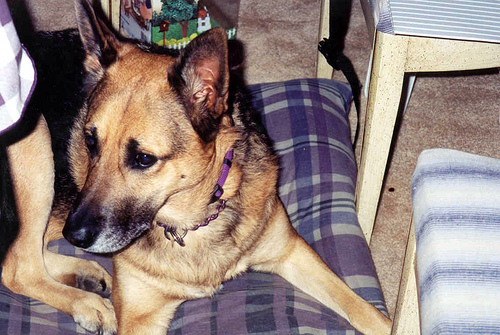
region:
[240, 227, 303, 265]
Small patch of brown fur on dog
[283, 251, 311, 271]
Small patch of brown fur on dog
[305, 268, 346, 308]
Small patch of brown fur on dog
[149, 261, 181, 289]
Small patch of brown fur on dog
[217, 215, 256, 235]
Small patch of brown fur on dog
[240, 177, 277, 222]
Small patch of brown fur on dog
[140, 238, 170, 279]
Small patch of brown fur on dog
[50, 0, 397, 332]
a dog is color brown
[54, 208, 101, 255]
the nose is black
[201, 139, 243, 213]
a purple collar on dog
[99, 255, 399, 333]
front legs of dog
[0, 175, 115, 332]
back legs of dog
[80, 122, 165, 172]
the eyes are color black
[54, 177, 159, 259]
snout of dog is black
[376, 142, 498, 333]
chair has a cushion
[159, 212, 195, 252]
a ring on collar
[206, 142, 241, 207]
dog wearing a purple collar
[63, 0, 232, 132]
dog with its ears perked up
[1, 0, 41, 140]
person wearing short sleeve shirt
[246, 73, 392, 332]
Purple pillow under a dog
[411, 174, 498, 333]
blue and white pillow on a chair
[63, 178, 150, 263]
dog with a black nose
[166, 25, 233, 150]
dogs ears are perked up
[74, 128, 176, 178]
dog with brown eyes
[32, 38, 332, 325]
a dog on a pillow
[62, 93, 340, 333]
a dog laying on a pillow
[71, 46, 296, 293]
a dog that is inside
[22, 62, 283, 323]
a dog laying inside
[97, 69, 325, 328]
a dog wearing a purple collar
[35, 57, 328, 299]
a large dog that is inside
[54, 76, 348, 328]
a large dog laying down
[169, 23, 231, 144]
ear of a big dog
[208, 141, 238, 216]
purple leash on a big dog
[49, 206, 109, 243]
nose of a sad looking dog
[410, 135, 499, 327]
patterned striped blue and white chair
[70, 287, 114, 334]
paw of a dog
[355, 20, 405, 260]
leg of a table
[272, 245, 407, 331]
leg of a big dog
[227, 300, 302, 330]
purple and grey patterned pillow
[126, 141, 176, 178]
eye of a big dog